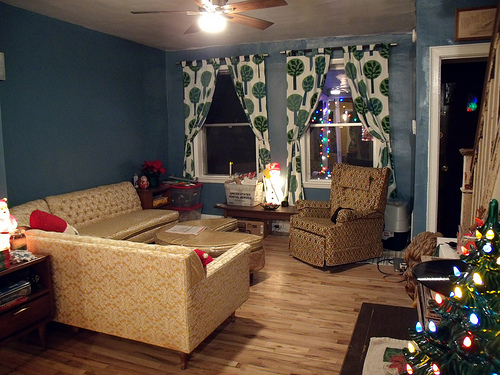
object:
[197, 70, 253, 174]
window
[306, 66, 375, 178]
window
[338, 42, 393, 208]
curtains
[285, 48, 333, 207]
curtains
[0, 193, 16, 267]
santa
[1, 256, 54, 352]
table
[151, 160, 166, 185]
poinsetta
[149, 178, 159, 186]
pot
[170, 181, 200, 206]
storage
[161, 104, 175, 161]
corner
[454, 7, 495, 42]
framed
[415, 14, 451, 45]
wall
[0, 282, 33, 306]
book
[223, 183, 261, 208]
bin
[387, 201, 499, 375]
tree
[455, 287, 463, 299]
lights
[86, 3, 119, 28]
ceiling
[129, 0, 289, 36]
fan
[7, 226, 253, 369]
couch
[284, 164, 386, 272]
chair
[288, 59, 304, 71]
green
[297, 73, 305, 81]
white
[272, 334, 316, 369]
floor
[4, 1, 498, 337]
room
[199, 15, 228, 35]
light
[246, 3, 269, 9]
brown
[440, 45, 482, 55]
white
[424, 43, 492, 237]
door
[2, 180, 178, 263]
sofa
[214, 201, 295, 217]
table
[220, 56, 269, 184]
curtain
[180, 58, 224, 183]
curtains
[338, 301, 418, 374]
rug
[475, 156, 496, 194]
railing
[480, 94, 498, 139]
stairway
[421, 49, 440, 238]
frame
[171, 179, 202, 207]
containers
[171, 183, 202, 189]
covers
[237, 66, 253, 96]
trees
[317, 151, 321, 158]
lights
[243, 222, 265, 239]
box